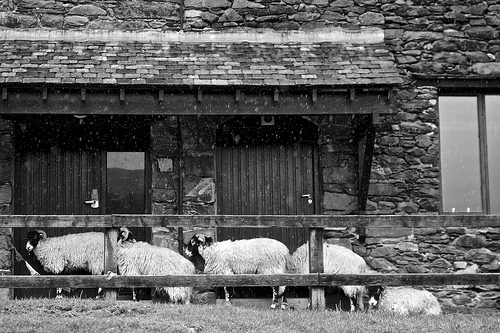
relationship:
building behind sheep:
[14, 11, 499, 315] [220, 176, 420, 324]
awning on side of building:
[3, 25, 408, 115] [5, 5, 492, 215]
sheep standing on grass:
[288, 233, 372, 310] [1, 299, 496, 331]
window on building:
[438, 77, 498, 218] [14, 11, 499, 315]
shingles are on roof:
[7, 48, 400, 99] [1, 24, 411, 96]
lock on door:
[299, 190, 316, 203] [217, 114, 321, 259]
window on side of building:
[428, 71, 499, 218] [14, 11, 499, 315]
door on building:
[75, 144, 190, 287] [14, 11, 499, 315]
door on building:
[219, 131, 319, 253] [14, 11, 499, 315]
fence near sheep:
[67, 208, 335, 287] [122, 229, 194, 278]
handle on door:
[84, 197, 96, 202] [14, 119, 101, 267]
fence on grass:
[0, 214, 500, 289] [1, 299, 496, 331]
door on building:
[219, 125, 319, 252] [14, 11, 499, 315]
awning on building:
[3, 25, 408, 115] [14, 11, 499, 315]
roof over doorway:
[0, 29, 404, 114] [84, 144, 149, 240]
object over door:
[256, 114, 280, 129] [217, 120, 322, 249]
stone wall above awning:
[0, 0, 498, 76] [3, 25, 408, 115]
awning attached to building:
[3, 25, 408, 115] [14, 1, 421, 316]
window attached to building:
[438, 77, 498, 218] [3, 0, 499, 300]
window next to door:
[103, 150, 145, 239] [16, 135, 101, 297]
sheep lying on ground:
[366, 273, 445, 313] [6, 292, 498, 331]